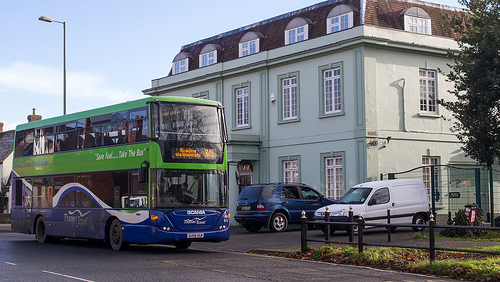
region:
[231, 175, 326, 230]
blue vehicle parked by building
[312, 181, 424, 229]
white van parked by building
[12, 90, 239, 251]
double decker bus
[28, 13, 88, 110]
streetlight above the bus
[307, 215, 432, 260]
fence in front of building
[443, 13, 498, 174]
green tress beside building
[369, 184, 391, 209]
side window of the van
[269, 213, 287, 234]
black tire on the blue vehicle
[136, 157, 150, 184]
mirror on the side of bus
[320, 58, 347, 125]
window on the building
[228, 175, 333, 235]
a small blue vehicle parked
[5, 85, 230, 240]
a green and blue bus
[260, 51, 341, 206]
several windows on a building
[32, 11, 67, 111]
a street light above the bus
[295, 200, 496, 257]
a small black fence next to the street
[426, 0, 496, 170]
a tree next to a building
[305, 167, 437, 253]
a white vehicle parked beside the fence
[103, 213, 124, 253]
a tire on the bus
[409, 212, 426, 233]
a tire on the vehicle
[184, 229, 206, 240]
a tag on a bus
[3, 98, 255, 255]
a double decker bus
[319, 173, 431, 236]
a white car parked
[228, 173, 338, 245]
a blue parked car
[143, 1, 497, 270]
a large light green building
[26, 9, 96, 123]
street lamp on a pole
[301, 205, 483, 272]
black railing with gold tops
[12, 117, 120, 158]
windows of a bus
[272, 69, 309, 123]
window on a building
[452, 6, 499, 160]
tree beside a building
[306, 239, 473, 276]
grass growing by the road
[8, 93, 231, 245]
Green and blue double decker bus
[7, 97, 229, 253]
Green and blue double decker bus in front of building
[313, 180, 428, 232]
White van is parked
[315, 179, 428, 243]
White van is parked next to blue SUV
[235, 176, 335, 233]
Blue SUV is parked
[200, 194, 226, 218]
Large black windshield on window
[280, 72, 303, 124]
Window on light green building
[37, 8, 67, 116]
Light post behind bus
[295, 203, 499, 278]
Black metal rail next to green grass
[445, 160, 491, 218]
Door to building near gate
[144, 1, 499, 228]
a three story building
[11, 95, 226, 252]
blue and green double decker bus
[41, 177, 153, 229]
blue and white painted swirl on side of bus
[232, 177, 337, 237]
blue car parked against building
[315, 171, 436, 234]
a white van parked backed in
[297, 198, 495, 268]
a wood fence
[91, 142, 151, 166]
writing in white letters on side of bus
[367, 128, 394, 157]
security cameras on side of building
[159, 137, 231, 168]
destination on front of the bus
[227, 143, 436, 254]
two vehicles parked by the building